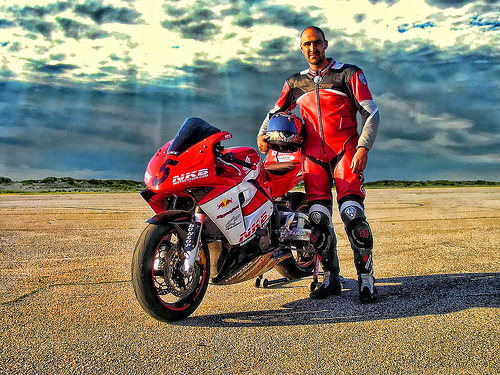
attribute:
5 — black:
[155, 161, 178, 187]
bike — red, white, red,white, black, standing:
[131, 119, 349, 319]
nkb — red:
[239, 212, 270, 240]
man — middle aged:
[253, 28, 389, 300]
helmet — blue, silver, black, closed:
[266, 112, 302, 149]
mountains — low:
[2, 169, 499, 195]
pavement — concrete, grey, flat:
[2, 187, 496, 373]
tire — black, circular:
[130, 218, 216, 321]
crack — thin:
[1, 272, 138, 310]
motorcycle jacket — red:
[256, 61, 379, 181]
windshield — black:
[169, 118, 228, 152]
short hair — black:
[299, 26, 325, 39]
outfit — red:
[259, 29, 399, 302]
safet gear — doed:
[257, 58, 402, 299]